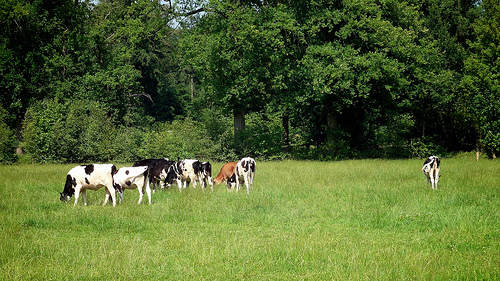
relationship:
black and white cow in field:
[224, 157, 257, 195] [0, 143, 484, 278]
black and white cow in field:
[224, 157, 257, 195] [4, 158, 500, 281]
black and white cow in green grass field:
[224, 157, 257, 195] [50, 130, 283, 251]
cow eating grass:
[61, 162, 117, 203] [3, 160, 498, 275]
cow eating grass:
[212, 160, 235, 186] [3, 160, 498, 275]